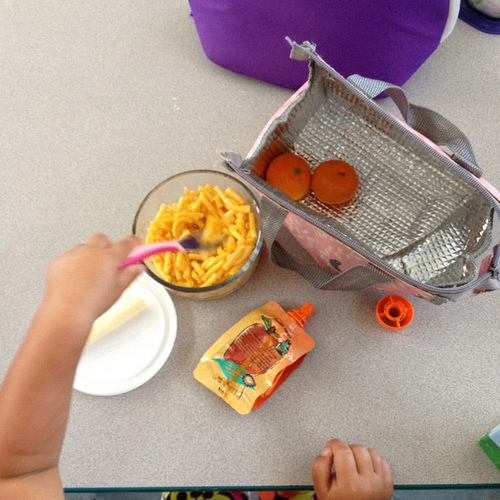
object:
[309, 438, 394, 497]
hand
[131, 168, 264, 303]
bowl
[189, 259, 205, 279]
cheese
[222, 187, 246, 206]
mac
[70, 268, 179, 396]
plate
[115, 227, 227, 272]
spoon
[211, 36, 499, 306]
picnic pack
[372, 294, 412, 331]
cap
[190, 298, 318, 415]
snack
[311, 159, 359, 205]
orange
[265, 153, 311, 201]
orange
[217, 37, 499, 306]
cooler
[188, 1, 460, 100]
cooler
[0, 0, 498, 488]
table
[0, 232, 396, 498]
person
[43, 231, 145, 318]
hands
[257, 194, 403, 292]
tote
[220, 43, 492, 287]
inside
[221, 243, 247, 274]
mac cheese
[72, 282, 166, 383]
lid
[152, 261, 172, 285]
mac cheese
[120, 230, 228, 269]
fork